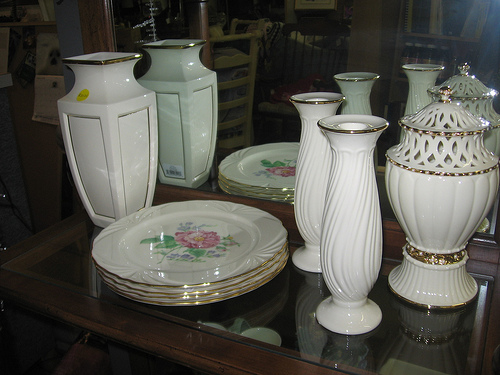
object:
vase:
[56, 52, 159, 229]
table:
[4, 191, 493, 375]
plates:
[91, 200, 287, 289]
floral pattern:
[140, 223, 238, 264]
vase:
[384, 85, 499, 309]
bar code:
[159, 164, 184, 177]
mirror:
[114, 1, 499, 229]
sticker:
[76, 88, 90, 101]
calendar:
[31, 74, 67, 126]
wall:
[54, 0, 79, 54]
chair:
[257, 22, 349, 140]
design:
[397, 133, 486, 165]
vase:
[316, 114, 389, 327]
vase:
[287, 93, 345, 273]